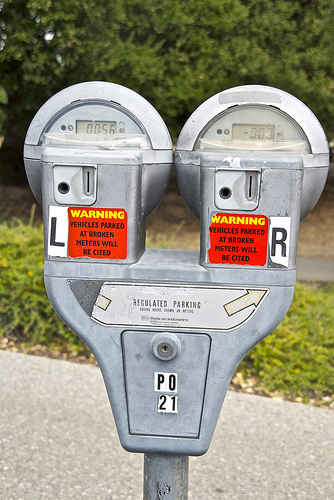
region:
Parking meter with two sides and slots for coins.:
[13, 70, 320, 476]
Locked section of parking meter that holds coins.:
[113, 322, 216, 448]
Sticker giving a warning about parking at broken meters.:
[199, 211, 279, 270]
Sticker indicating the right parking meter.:
[266, 208, 291, 272]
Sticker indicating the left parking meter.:
[39, 205, 70, 263]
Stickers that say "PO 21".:
[148, 367, 185, 418]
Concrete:
[5, 376, 317, 486]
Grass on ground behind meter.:
[239, 286, 333, 383]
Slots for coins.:
[76, 164, 264, 209]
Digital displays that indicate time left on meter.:
[70, 118, 288, 145]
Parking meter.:
[24, 164, 300, 486]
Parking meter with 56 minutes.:
[76, 86, 148, 153]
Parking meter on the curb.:
[150, 67, 320, 328]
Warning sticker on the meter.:
[36, 75, 213, 291]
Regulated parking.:
[118, 280, 240, 341]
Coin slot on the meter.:
[69, 163, 113, 204]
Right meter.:
[242, 195, 321, 273]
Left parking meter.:
[39, 194, 100, 313]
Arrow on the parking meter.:
[211, 274, 319, 343]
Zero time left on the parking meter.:
[225, 115, 321, 193]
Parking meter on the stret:
[18, 63, 331, 498]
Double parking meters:
[5, 69, 329, 274]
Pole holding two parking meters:
[126, 455, 201, 496]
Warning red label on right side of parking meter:
[197, 202, 274, 272]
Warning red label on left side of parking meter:
[60, 199, 128, 265]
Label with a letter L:
[40, 198, 72, 262]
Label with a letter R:
[266, 213, 295, 268]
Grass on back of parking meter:
[255, 282, 329, 391]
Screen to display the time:
[69, 114, 130, 143]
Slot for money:
[243, 167, 259, 199]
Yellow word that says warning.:
[208, 211, 268, 225]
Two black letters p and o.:
[143, 367, 182, 393]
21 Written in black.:
[144, 391, 192, 412]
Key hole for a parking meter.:
[39, 315, 287, 368]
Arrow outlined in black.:
[218, 283, 270, 324]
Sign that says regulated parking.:
[114, 298, 204, 311]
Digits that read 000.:
[229, 128, 286, 140]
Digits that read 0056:
[73, 120, 118, 133]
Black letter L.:
[31, 210, 64, 253]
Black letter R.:
[268, 213, 293, 270]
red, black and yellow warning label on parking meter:
[62, 200, 125, 262]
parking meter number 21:
[143, 391, 182, 419]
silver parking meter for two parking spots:
[42, 78, 312, 456]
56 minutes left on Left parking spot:
[69, 115, 128, 144]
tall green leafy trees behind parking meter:
[35, 8, 317, 70]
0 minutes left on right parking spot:
[225, 115, 284, 149]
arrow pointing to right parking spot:
[216, 281, 276, 326]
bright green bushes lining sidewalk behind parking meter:
[261, 343, 326, 386]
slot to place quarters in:
[237, 164, 272, 205]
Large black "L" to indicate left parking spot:
[43, 200, 75, 260]